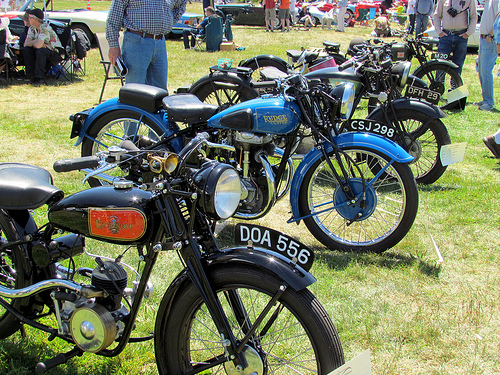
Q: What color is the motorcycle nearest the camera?
A: Black.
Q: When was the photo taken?
A: Daytime.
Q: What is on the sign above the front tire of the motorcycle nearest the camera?
A: DOA556.